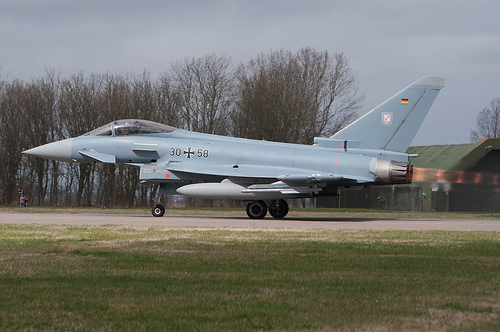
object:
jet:
[15, 72, 447, 220]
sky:
[0, 0, 500, 136]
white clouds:
[401, 35, 473, 72]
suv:
[19, 75, 447, 217]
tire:
[268, 197, 289, 218]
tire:
[245, 197, 270, 219]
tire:
[152, 204, 166, 216]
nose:
[22, 138, 89, 172]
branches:
[0, 49, 352, 208]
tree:
[2, 79, 59, 218]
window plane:
[11, 116, 188, 213]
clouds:
[0, 0, 498, 88]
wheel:
[268, 199, 289, 219]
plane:
[16, 71, 444, 225]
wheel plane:
[148, 203, 170, 225]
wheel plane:
[243, 196, 273, 230]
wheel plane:
[268, 197, 293, 229]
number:
[169, 148, 182, 157]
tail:
[326, 74, 449, 149]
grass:
[0, 213, 500, 332]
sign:
[168, 146, 210, 160]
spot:
[420, 313, 500, 332]